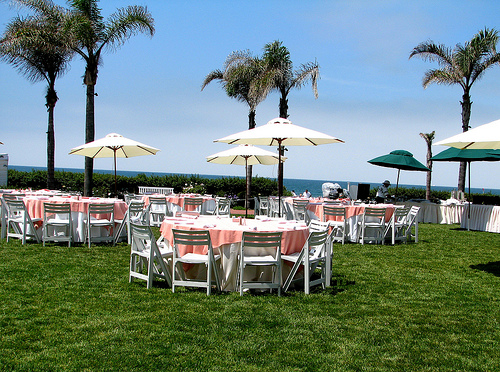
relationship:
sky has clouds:
[1, 3, 496, 186] [86, 77, 398, 174]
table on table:
[158, 217, 309, 294] [158, 202, 351, 308]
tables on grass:
[13, 178, 407, 283] [6, 246, 485, 372]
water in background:
[15, 151, 438, 208] [13, 98, 496, 213]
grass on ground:
[6, 246, 485, 372] [7, 189, 493, 357]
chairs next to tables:
[111, 213, 232, 294] [13, 178, 407, 283]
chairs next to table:
[111, 213, 232, 294] [158, 202, 351, 308]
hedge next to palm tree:
[10, 162, 317, 206] [208, 41, 285, 97]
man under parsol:
[365, 171, 411, 208] [213, 117, 344, 218]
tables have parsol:
[13, 178, 407, 283] [213, 117, 344, 218]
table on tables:
[158, 217, 309, 294] [13, 178, 407, 283]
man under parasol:
[365, 171, 411, 208] [359, 118, 443, 192]